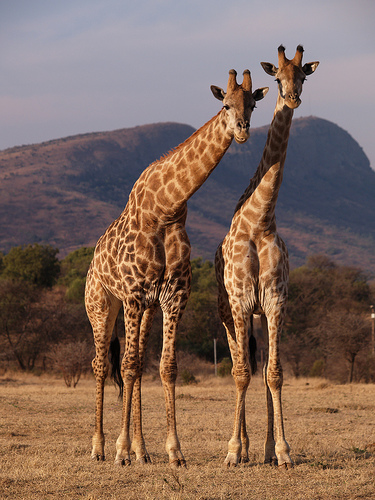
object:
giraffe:
[85, 68, 254, 467]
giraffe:
[213, 43, 318, 474]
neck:
[121, 123, 234, 206]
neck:
[243, 91, 290, 232]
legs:
[84, 293, 118, 470]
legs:
[266, 302, 285, 474]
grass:
[6, 469, 370, 498]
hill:
[10, 114, 370, 245]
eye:
[223, 104, 230, 111]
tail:
[108, 329, 120, 390]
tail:
[249, 315, 257, 374]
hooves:
[164, 442, 186, 467]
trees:
[0, 244, 373, 380]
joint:
[122, 354, 139, 381]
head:
[204, 70, 270, 143]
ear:
[210, 85, 227, 101]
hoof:
[164, 438, 185, 469]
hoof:
[115, 442, 128, 465]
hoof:
[276, 440, 293, 469]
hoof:
[224, 443, 240, 466]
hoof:
[90, 434, 106, 460]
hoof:
[133, 438, 151, 464]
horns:
[242, 71, 251, 85]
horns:
[277, 45, 286, 66]